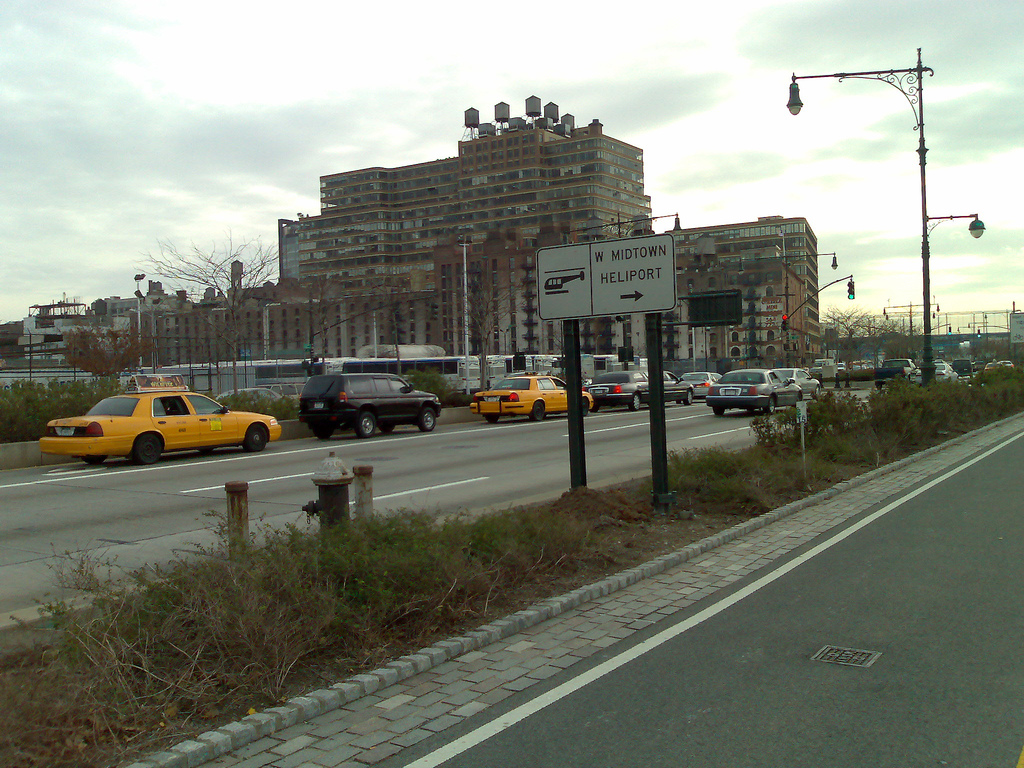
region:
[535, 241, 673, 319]
a black and white sign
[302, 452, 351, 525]
a grey metal fire hydrant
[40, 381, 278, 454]
a yellow taxi cab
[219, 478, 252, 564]
a metal street post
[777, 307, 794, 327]
a red street light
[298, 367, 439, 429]
a black suv vehicle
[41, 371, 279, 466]
a yellow taxi driving to the airport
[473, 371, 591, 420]
a yellow taxi driving to the airport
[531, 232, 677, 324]
a heliport sign near the highway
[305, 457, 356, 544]
a fire hydrant hear the highway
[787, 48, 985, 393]
street lamps near the highway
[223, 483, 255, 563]
a metal pipe near the highway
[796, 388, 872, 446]
a bush in tall grass near the highway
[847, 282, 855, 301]
a street light above the highway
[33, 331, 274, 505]
a yellow taxi cab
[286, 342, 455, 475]
this is a black SUV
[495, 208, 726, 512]
a white road sign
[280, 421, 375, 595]
a rusty fire hydrant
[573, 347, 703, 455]
this is a black limousine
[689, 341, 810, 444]
this is a black town car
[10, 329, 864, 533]
the cars are stopped at a light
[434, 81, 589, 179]
these are water towers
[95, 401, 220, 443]
A yellow taxi cab on the street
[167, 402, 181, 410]
The rear window rolled down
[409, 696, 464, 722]
Side of the street cobaled with stone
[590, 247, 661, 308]
A direction sign post in the center of two roads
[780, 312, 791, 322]
A red traffic light shining on the road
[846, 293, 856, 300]
A green traffic light above the cars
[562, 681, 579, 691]
A white line on the side of the road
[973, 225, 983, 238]
A street lamp hanging above the road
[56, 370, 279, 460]
a car on a street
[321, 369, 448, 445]
a car on a street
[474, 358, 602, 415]
a car on a street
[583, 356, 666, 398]
a car on a street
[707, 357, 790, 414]
a car on a street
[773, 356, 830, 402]
a car on a street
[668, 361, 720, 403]
a car on a street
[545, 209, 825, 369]
a building in a city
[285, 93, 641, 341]
a building in a city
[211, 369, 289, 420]
a car in a parking lot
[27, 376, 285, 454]
The yellow cab in the back.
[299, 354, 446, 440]
The black truck on the left.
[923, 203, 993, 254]
The light hanging on the pole.